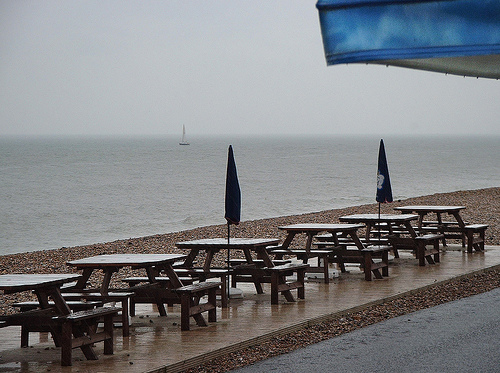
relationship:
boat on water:
[179, 123, 190, 145] [38, 92, 495, 291]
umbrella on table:
[373, 136, 390, 246] [339, 192, 451, 273]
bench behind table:
[170, 276, 220, 331] [53, 249, 210, 311]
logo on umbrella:
[375, 170, 386, 191] [374, 136, 400, 216]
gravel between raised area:
[383, 294, 413, 318] [1, 186, 498, 371]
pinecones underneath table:
[140, 312, 179, 329] [64, 250, 188, 277]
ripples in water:
[30, 175, 176, 227] [5, 148, 203, 233]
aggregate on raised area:
[147, 264, 499, 371] [1, 186, 498, 371]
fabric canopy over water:
[316, 0, 498, 78] [0, 136, 497, 371]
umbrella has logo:
[373, 136, 390, 246] [376, 168, 383, 191]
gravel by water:
[138, 238, 172, 252] [1, 135, 498, 194]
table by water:
[0, 273, 112, 367] [1, 132, 498, 254]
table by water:
[67, 252, 220, 327] [1, 132, 498, 254]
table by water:
[172, 235, 309, 308] [1, 132, 498, 254]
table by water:
[281, 217, 392, 287] [1, 132, 498, 254]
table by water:
[345, 205, 440, 270] [1, 132, 498, 254]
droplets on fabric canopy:
[327, 59, 499, 85] [316, 0, 498, 78]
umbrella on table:
[222, 145, 244, 226] [79, 230, 222, 320]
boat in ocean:
[179, 122, 191, 145] [83, 131, 137, 202]